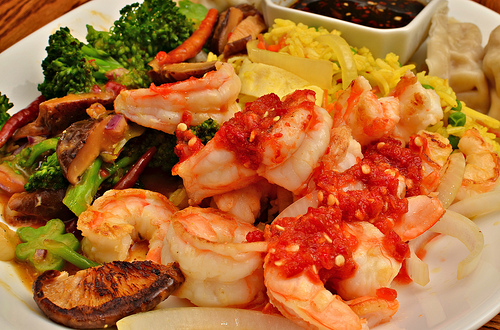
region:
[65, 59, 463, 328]
Pieces of large pink shrimp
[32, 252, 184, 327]
Black and brown piece of meat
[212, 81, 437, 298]
Red sauce on shrimp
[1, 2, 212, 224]
Green broccoli on plate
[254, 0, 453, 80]
White square bowl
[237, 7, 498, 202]
Yellow vegetable fried rice on the plate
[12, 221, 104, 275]
Green piece of vegetable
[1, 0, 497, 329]
White plate with food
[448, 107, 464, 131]
Small green pea on white plate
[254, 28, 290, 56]
Small piece of orange carrot in rice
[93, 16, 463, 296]
This is an Asian meal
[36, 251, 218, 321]
A mushroom that has been grilled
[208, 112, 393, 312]
Shrimp with a spicy sauce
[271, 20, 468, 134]
Fried rice has peas in it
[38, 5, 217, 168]
Broccoli is green and carrots are orange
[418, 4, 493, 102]
These are wontons cooked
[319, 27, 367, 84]
A sliver of onion in the fried rice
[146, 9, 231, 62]
A small and thin carrot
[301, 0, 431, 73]
This is a thick spicy sauce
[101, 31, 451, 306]
This dish looks delicious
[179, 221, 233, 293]
Piece of shrimp on plate.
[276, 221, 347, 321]
Piece of shrimp on plate.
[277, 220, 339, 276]
Red sauce on top of shrimp.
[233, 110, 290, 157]
Piece of shrimp on plate.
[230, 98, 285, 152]
Red sauce on top of shrimp.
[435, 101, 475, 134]
Green pea on top of plate.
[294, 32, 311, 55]
Rice on top of plate.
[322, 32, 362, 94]
Piece of white onion on top of plate.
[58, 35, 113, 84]
Green broccoli on plate.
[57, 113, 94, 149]
Piece of brown mushroom on plate.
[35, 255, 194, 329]
A small, burnt wedge.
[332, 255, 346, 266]
A yellow pepper seed.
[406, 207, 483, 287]
An onion shaped like a "C."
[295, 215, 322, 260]
Marinara sauce slathered on some shrimp.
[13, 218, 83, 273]
A green star shaped vegetable.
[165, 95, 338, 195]
A large piece of shrimp.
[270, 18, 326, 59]
Fried rice in the corner of the bowl.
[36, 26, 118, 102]
A piece of cooked broccoli.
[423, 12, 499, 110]
Two egg rolls at the edge of the plate.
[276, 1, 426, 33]
Dipping sauce in a bowl.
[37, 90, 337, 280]
This is an asian dish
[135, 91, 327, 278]
This is fresh shrimp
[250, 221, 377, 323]
This is chili sauce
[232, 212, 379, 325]
The sauce is red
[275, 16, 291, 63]
This is a hunk of rice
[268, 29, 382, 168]
The rice is yellow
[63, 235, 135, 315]
This is a mushroom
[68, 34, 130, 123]
This is sauted broccoli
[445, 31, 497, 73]
These are two dumplings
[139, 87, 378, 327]
This is a plate